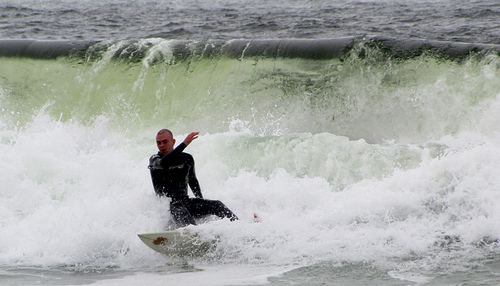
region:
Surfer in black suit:
[122, 99, 264, 280]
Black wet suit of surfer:
[139, 148, 251, 233]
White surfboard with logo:
[115, 221, 232, 266]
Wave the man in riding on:
[4, 29, 496, 224]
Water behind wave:
[1, 0, 498, 34]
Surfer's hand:
[177, 129, 207, 149]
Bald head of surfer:
[151, 122, 180, 157]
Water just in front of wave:
[0, 267, 498, 281]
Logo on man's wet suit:
[160, 159, 189, 175]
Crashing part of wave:
[5, 118, 499, 258]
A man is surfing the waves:
[136, 125, 267, 260]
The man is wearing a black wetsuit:
[141, 126, 261, 226]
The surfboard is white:
[135, 225, 262, 262]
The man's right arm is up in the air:
[148, 126, 212, 170]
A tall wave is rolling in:
[40, 32, 265, 128]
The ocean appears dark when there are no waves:
[251, 5, 468, 32]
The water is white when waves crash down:
[266, 108, 463, 211]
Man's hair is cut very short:
[148, 123, 179, 156]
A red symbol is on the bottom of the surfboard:
[148, 234, 169, 248]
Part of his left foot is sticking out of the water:
[248, 210, 264, 224]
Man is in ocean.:
[138, 121, 247, 278]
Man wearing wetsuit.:
[153, 142, 223, 244]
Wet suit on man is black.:
[143, 122, 238, 278]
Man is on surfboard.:
[140, 162, 217, 267]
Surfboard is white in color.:
[122, 154, 251, 261]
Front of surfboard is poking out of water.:
[121, 210, 222, 277]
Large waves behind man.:
[63, 17, 310, 174]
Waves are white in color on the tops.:
[43, 86, 379, 248]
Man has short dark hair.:
[148, 125, 177, 146]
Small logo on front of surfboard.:
[145, 228, 177, 253]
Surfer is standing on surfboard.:
[134, 121, 278, 259]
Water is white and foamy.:
[1, 28, 498, 284]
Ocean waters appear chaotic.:
[1, 27, 499, 283]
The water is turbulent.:
[2, 28, 499, 280]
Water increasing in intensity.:
[2, 2, 497, 282]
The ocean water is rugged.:
[0, 0, 499, 284]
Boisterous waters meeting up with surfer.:
[0, 1, 499, 284]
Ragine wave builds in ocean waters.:
[1, 3, 498, 284]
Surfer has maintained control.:
[136, 121, 280, 253]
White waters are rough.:
[0, 64, 499, 260]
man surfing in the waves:
[3, 8, 485, 270]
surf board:
[133, 221, 235, 261]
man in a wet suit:
[148, 128, 234, 223]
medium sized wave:
[14, 24, 499, 248]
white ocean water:
[227, 128, 487, 248]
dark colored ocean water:
[10, 0, 492, 65]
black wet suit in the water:
[150, 152, 225, 218]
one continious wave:
[0, 35, 490, 145]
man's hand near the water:
[181, 126, 191, 146]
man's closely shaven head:
[157, 126, 176, 153]